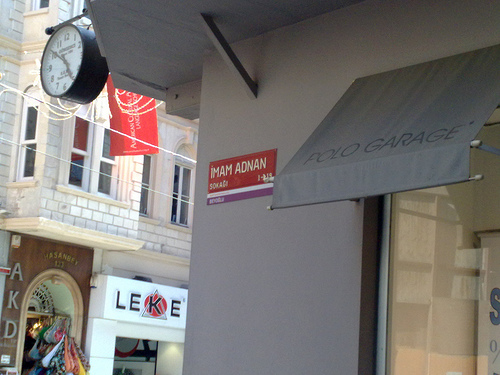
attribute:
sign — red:
[204, 148, 281, 206]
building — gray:
[83, 1, 498, 373]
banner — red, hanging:
[107, 73, 160, 157]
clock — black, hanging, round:
[38, 22, 109, 105]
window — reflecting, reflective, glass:
[374, 126, 499, 374]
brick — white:
[70, 206, 81, 216]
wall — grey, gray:
[183, 4, 402, 374]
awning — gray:
[267, 43, 500, 211]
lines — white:
[1, 80, 197, 207]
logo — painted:
[115, 284, 185, 320]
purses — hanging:
[27, 312, 90, 374]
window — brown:
[10, 232, 94, 374]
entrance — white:
[82, 272, 188, 375]